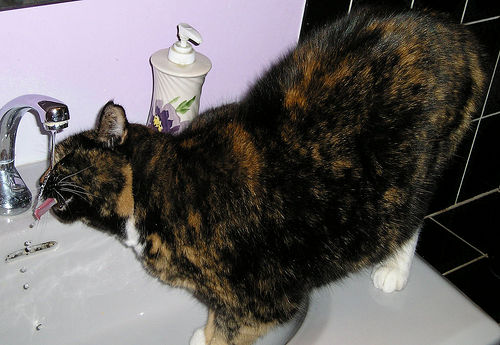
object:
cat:
[23, 1, 492, 344]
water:
[50, 132, 58, 164]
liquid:
[164, 79, 191, 93]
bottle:
[146, 21, 212, 136]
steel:
[0, 166, 35, 216]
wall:
[1, 5, 253, 101]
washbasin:
[322, 267, 500, 345]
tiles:
[430, 4, 498, 259]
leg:
[190, 283, 310, 345]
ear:
[94, 100, 129, 146]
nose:
[38, 178, 45, 188]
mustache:
[41, 188, 57, 198]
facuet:
[31, 134, 56, 215]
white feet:
[370, 260, 410, 293]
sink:
[1, 160, 498, 345]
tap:
[0, 94, 71, 216]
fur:
[271, 92, 374, 203]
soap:
[146, 47, 212, 135]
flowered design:
[146, 93, 199, 134]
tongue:
[33, 197, 56, 221]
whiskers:
[55, 157, 109, 216]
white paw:
[191, 327, 205, 345]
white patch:
[124, 216, 148, 255]